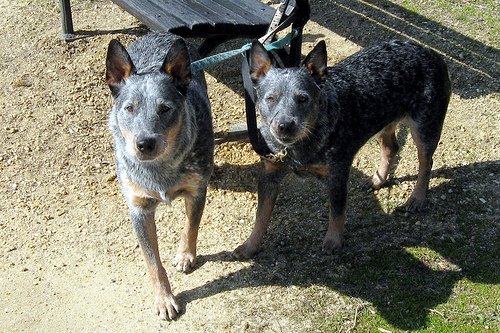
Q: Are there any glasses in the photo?
A: No, there are no glasses.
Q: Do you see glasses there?
A: No, there are no glasses.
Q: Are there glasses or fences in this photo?
A: No, there are no glasses or fences.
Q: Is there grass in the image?
A: Yes, there is grass.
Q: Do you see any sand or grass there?
A: Yes, there is grass.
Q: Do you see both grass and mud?
A: No, there is grass but no mud.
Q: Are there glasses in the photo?
A: No, there are no glasses.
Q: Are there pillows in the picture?
A: No, there are no pillows.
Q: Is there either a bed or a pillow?
A: No, there are no pillows or beds.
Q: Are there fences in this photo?
A: No, there are no fences.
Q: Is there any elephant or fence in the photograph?
A: No, there are no fences or elephants.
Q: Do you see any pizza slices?
A: No, there are no pizza slices.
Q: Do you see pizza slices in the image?
A: No, there are no pizza slices.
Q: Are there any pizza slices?
A: No, there are no pizza slices.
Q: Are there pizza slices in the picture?
A: No, there are no pizza slices.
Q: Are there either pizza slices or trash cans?
A: No, there are no pizza slices or trash cans.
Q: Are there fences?
A: No, there are no fences.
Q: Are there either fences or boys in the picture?
A: No, there are no fences or boys.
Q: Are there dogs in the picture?
A: Yes, there is a dog.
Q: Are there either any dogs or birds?
A: Yes, there is a dog.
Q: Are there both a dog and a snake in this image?
A: No, there is a dog but no snakes.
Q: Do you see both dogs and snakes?
A: No, there is a dog but no snakes.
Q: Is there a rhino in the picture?
A: No, there are no rhinos.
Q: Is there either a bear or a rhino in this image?
A: No, there are no rhinos or bears.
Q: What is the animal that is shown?
A: The animal is a dog.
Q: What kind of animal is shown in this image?
A: The animal is a dog.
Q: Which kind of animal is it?
A: The animal is a dog.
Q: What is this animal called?
A: This is a dog.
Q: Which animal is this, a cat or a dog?
A: This is a dog.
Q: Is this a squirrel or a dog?
A: This is a dog.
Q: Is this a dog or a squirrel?
A: This is a dog.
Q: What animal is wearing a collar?
A: The dog is wearing a collar.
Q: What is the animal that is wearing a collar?
A: The animal is a dog.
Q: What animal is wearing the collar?
A: The animal is a dog.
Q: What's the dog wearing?
A: The dog is wearing a collar.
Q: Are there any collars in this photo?
A: Yes, there is a collar.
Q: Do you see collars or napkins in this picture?
A: Yes, there is a collar.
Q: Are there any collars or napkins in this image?
A: Yes, there is a collar.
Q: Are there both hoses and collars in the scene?
A: No, there is a collar but no hoses.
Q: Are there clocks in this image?
A: No, there are no clocks.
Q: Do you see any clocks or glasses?
A: No, there are no clocks or glasses.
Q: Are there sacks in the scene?
A: No, there are no sacks.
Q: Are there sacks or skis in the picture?
A: No, there are no sacks or skis.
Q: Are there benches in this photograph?
A: Yes, there is a bench.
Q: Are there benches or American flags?
A: Yes, there is a bench.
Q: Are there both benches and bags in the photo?
A: No, there is a bench but no bags.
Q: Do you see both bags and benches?
A: No, there is a bench but no bags.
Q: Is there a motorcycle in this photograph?
A: No, there are no motorcycles.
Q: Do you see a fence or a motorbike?
A: No, there are no motorcycles or fences.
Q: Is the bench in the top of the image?
A: Yes, the bench is in the top of the image.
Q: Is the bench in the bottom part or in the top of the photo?
A: The bench is in the top of the image.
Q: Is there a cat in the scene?
A: No, there are no cats.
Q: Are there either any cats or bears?
A: No, there are no cats or bears.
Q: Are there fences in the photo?
A: No, there are no fences.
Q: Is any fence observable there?
A: No, there are no fences.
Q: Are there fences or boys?
A: No, there are no fences or boys.